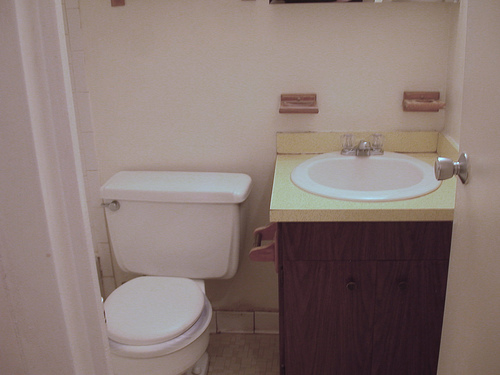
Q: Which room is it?
A: It is a bathroom.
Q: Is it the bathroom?
A: Yes, it is the bathroom.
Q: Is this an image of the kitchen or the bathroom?
A: It is showing the bathroom.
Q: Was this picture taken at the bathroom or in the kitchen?
A: It was taken at the bathroom.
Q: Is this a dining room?
A: No, it is a bathroom.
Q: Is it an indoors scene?
A: Yes, it is indoors.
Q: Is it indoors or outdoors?
A: It is indoors.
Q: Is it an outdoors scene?
A: No, it is indoors.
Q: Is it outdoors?
A: No, it is indoors.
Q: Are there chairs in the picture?
A: No, there are no chairs.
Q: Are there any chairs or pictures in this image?
A: No, there are no chairs or pictures.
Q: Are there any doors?
A: Yes, there is a door.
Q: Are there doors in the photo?
A: Yes, there is a door.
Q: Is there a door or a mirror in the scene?
A: Yes, there is a door.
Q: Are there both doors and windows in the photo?
A: No, there is a door but no windows.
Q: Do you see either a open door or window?
A: Yes, there is an open door.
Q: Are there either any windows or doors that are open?
A: Yes, the door is open.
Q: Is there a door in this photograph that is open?
A: Yes, there is an open door.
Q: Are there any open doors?
A: Yes, there is an open door.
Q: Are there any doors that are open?
A: Yes, there is a door that is open.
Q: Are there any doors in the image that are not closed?
A: Yes, there is a open door.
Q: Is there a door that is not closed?
A: Yes, there is a open door.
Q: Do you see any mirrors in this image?
A: No, there are no mirrors.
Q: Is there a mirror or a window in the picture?
A: No, there are no mirrors or windows.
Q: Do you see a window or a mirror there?
A: No, there are no mirrors or windows.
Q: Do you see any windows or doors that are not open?
A: No, there is a door but it is open.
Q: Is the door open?
A: Yes, the door is open.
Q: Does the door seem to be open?
A: Yes, the door is open.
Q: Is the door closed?
A: No, the door is open.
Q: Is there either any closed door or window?
A: No, there is a door but it is open.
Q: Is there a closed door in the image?
A: No, there is a door but it is open.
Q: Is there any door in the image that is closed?
A: No, there is a door but it is open.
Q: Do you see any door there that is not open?
A: No, there is a door but it is open.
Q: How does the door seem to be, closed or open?
A: The door is open.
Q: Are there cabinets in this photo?
A: Yes, there is a cabinet.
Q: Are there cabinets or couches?
A: Yes, there is a cabinet.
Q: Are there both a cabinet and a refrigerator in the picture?
A: No, there is a cabinet but no refrigerators.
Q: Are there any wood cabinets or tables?
A: Yes, there is a wood cabinet.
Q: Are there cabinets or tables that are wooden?
A: Yes, the cabinet is wooden.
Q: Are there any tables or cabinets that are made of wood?
A: Yes, the cabinet is made of wood.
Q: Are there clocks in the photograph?
A: No, there are no clocks.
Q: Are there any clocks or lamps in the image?
A: No, there are no clocks or lamps.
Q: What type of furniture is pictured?
A: The furniture is a cabinet.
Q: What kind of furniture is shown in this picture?
A: The furniture is a cabinet.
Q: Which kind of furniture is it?
A: The piece of furniture is a cabinet.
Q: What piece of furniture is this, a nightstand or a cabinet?
A: This is a cabinet.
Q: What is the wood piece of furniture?
A: The piece of furniture is a cabinet.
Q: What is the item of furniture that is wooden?
A: The piece of furniture is a cabinet.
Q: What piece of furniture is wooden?
A: The piece of furniture is a cabinet.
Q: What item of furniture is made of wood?
A: The piece of furniture is a cabinet.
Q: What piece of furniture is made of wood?
A: The piece of furniture is a cabinet.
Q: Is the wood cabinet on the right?
A: Yes, the cabinet is on the right of the image.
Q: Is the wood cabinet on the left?
A: No, the cabinet is on the right of the image.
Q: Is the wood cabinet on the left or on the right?
A: The cabinet is on the right of the image.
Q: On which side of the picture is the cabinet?
A: The cabinet is on the right of the image.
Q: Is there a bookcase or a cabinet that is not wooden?
A: No, there is a cabinet but it is wooden.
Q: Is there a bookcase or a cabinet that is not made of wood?
A: No, there is a cabinet but it is made of wood.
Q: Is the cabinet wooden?
A: Yes, the cabinet is wooden.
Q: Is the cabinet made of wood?
A: Yes, the cabinet is made of wood.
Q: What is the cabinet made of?
A: The cabinet is made of wood.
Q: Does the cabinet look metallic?
A: No, the cabinet is wooden.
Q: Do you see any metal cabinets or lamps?
A: No, there is a cabinet but it is wooden.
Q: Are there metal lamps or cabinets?
A: No, there is a cabinet but it is wooden.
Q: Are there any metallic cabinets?
A: No, there is a cabinet but it is wooden.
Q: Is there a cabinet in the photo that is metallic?
A: No, there is a cabinet but it is wooden.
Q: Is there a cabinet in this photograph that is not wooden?
A: No, there is a cabinet but it is wooden.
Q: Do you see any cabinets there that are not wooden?
A: No, there is a cabinet but it is wooden.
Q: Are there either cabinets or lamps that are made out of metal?
A: No, there is a cabinet but it is made of wood.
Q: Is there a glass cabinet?
A: No, there is a cabinet but it is made of wood.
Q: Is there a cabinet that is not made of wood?
A: No, there is a cabinet but it is made of wood.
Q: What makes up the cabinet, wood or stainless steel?
A: The cabinet is made of wood.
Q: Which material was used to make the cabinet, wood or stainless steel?
A: The cabinet is made of wood.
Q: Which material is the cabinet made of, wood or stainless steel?
A: The cabinet is made of wood.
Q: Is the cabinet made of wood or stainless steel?
A: The cabinet is made of wood.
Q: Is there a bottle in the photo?
A: No, there are no bottles.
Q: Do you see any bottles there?
A: No, there are no bottles.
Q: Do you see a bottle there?
A: No, there are no bottles.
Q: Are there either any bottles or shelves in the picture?
A: No, there are no bottles or shelves.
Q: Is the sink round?
A: Yes, the sink is round.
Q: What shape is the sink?
A: The sink is round.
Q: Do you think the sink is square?
A: No, the sink is round.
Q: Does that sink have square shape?
A: No, the sink is round.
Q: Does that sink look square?
A: No, the sink is round.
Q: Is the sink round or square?
A: The sink is round.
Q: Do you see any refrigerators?
A: No, there are no refrigerators.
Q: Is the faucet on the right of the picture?
A: Yes, the faucet is on the right of the image.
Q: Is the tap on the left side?
A: No, the tap is on the right of the image.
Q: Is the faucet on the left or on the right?
A: The faucet is on the right of the image.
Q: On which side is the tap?
A: The tap is on the right of the image.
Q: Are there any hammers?
A: No, there are no hammers.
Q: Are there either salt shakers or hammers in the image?
A: No, there are no hammers or salt shakers.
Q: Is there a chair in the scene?
A: No, there are no chairs.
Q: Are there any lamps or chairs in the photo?
A: No, there are no chairs or lamps.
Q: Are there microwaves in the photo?
A: No, there are no microwaves.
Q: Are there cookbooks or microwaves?
A: No, there are no microwaves or cookbooks.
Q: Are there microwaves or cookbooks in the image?
A: No, there are no microwaves or cookbooks.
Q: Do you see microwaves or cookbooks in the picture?
A: No, there are no microwaves or cookbooks.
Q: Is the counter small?
A: Yes, the counter is small.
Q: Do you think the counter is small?
A: Yes, the counter is small.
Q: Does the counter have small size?
A: Yes, the counter is small.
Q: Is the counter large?
A: No, the counter is small.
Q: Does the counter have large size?
A: No, the counter is small.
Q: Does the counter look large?
A: No, the counter is small.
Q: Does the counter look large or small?
A: The counter is small.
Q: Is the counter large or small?
A: The counter is small.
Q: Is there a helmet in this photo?
A: No, there are no helmets.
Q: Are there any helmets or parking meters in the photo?
A: No, there are no helmets or parking meters.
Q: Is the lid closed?
A: Yes, the lid is closed.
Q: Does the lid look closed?
A: Yes, the lid is closed.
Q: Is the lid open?
A: No, the lid is closed.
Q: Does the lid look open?
A: No, the lid is closed.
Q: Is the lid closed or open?
A: The lid is closed.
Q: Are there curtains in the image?
A: No, there are no curtains.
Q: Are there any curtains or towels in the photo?
A: No, there are no curtains or towels.